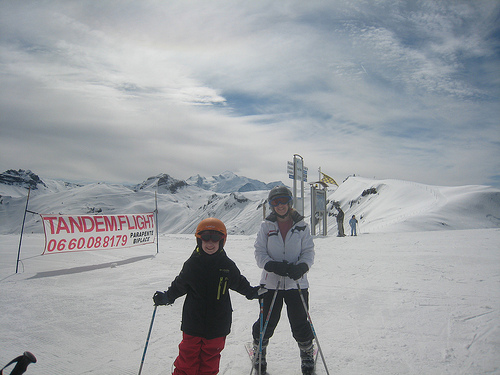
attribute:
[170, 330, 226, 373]
pants — red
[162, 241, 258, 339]
coat — black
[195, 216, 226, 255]
helmet — orange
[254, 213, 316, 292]
coat — white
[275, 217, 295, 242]
shirt — pink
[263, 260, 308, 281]
gloves — black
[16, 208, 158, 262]
banner — white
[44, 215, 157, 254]
writing — red, black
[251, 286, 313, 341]
pants — black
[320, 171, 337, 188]
flag — yellow, checkered, black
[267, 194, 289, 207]
goggles — dark, black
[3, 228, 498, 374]
ground — snow, white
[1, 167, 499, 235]
mountains — snow covered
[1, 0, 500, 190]
sky — cloudy, blue